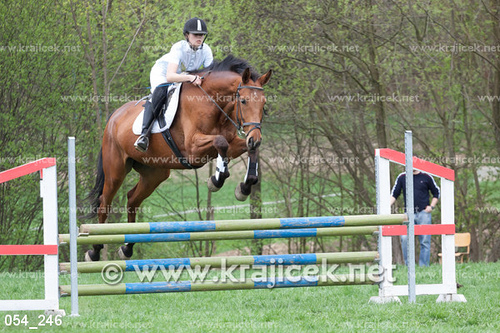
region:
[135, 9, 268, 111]
A girl on a horse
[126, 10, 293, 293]
A girl on a horse jumping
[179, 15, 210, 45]
Girl is wearing a helmet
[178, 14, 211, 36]
The helmet is black with a white stripe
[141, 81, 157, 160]
Tall black boots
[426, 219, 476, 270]
A yellow chair with no one sitting in it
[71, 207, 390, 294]
Blue and yellow poles for jumping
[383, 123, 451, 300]
A man in a blue shirt and jeans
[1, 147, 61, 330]
Red and white fencing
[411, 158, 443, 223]
Man with his hand in his pocket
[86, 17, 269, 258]
woman riding a horse in a competition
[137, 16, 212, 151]
woman on a horse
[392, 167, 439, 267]
man standing in the background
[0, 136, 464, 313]
equestrian hurdle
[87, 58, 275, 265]
horse jumping over a hurdle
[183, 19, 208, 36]
black helmet on the horse rider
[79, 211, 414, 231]
green and blue striped hurdle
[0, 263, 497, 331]
green grass on the ground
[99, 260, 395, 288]
watermark text of a website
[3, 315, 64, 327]
numbers in the lower left corner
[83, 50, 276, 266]
A brown horse with a black mane.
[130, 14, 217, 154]
A rider on a horse.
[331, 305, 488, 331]
Green blades of grass.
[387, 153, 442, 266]
A man observing the horse.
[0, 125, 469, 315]
A jump for horses.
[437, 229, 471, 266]
A brown wood chair.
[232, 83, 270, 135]
A harness on a horse's head.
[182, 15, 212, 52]
A black and white rider's hat.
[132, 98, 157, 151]
Tall black riding boots.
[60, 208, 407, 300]
Green and blue pylons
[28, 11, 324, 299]
Horse jockey and horse jumping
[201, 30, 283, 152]
Brown horse with black mane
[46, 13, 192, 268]
Horse's hind legs and hooves in air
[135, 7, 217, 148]
Female horse jockey in black helmet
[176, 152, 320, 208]
Horses front hooves poised to jump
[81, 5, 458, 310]
Man watching horse and jockey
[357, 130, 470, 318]
Man with blue top and jeans at a distance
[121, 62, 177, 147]
Black horse jockey boots in stirrups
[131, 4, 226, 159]
Female jockey in light colored clothes and black boots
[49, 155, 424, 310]
Green and blue horse hurdle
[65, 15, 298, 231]
Brown horse with black hair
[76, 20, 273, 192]
woman riding a horse wearing a black hat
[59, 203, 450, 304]
green and blue poles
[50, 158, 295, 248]
the horses shoes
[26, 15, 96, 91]
trees in the back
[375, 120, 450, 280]
a man standing in the back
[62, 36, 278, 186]
horse about to jump over a gate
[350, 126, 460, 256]
red and white gate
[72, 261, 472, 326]
field of green grass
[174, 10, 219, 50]
black and white hat